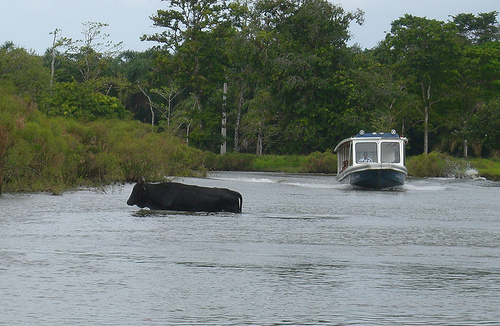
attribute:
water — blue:
[61, 217, 316, 307]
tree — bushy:
[138, 2, 256, 157]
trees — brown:
[156, 9, 493, 139]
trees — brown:
[2, 21, 169, 121]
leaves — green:
[50, 83, 117, 116]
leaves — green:
[330, 69, 362, 99]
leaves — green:
[168, 7, 213, 39]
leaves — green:
[464, 14, 494, 42]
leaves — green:
[201, 107, 223, 143]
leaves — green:
[228, 50, 295, 100]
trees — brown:
[198, 33, 341, 118]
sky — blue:
[12, 0, 187, 67]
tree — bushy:
[1, 116, 96, 196]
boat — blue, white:
[330, 129, 412, 188]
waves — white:
[214, 171, 456, 193]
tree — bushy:
[106, 120, 178, 181]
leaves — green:
[2, 0, 499, 181]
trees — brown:
[4, 1, 498, 188]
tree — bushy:
[370, 14, 477, 154]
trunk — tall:
[210, 64, 272, 157]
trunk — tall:
[420, 66, 447, 162]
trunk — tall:
[452, 133, 487, 170]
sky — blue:
[0, 2, 497, 77]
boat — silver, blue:
[298, 109, 458, 228]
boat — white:
[315, 120, 419, 197]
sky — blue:
[2, 0, 497, 62]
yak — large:
[127, 183, 244, 215]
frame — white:
[349, 130, 407, 164]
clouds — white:
[9, 0, 50, 42]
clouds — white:
[359, 2, 379, 32]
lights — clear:
[355, 121, 400, 138]